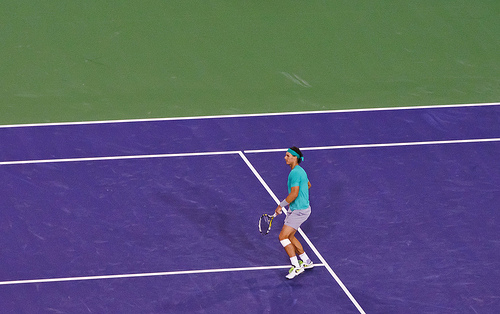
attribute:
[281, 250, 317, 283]
shoes — white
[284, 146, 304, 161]
headband — green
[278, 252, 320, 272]
sock — white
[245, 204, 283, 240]
racket — held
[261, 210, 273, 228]
tennis racket — large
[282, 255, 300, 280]
shoe — white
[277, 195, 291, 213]
gray wristband — grey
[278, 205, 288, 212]
wristband — gray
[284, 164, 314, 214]
shirt — blue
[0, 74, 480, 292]
line — white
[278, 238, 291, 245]
brace — white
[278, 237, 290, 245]
band — white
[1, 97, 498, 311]
court — purple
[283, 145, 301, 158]
headband — blue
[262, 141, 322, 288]
player — professional, tennis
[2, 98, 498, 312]
tennis court — purple